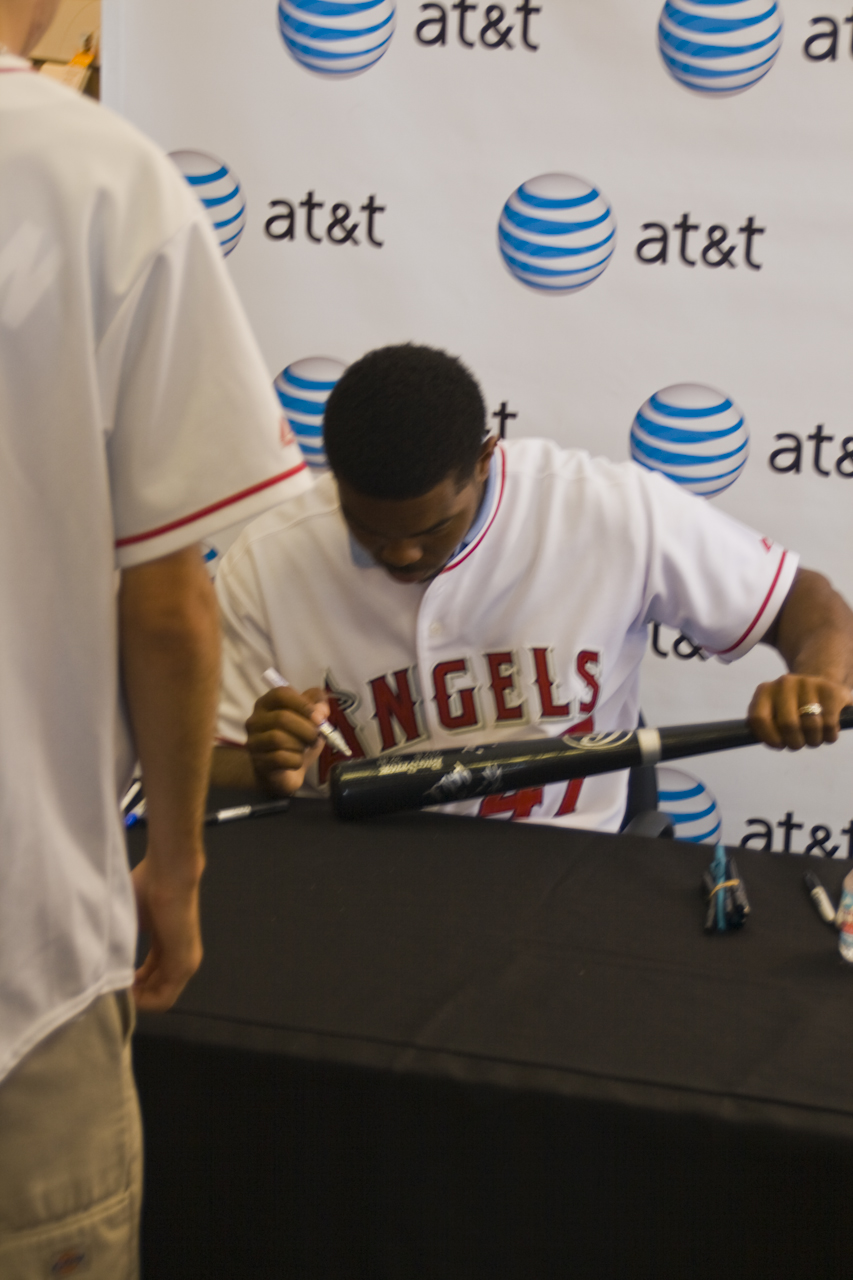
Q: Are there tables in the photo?
A: Yes, there is a table.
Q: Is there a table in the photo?
A: Yes, there is a table.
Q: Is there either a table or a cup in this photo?
A: Yes, there is a table.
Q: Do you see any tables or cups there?
A: Yes, there is a table.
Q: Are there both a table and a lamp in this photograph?
A: No, there is a table but no lamps.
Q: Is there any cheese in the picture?
A: No, there is no cheese.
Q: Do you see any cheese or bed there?
A: No, there are no cheese or beds.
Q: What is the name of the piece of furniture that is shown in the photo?
A: The piece of furniture is a table.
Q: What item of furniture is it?
A: The piece of furniture is a table.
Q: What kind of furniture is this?
A: This is a table.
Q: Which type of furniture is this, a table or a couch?
A: This is a table.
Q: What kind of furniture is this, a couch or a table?
A: This is a table.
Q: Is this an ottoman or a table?
A: This is a table.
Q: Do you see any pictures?
A: No, there are no pictures.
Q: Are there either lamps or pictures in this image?
A: No, there are no pictures or lamps.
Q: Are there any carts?
A: No, there are no carts.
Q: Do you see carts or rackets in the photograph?
A: No, there are no carts or rackets.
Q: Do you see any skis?
A: No, there are no skis.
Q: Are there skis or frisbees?
A: No, there are no skis or frisbees.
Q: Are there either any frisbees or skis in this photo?
A: No, there are no skis or frisbees.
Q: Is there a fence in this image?
A: No, there are no fences.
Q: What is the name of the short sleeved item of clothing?
A: The clothing item is a shirt.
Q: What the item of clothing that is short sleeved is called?
A: The clothing item is a shirt.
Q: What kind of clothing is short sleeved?
A: The clothing is a shirt.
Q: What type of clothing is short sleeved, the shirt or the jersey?
A: The shirt is short sleeved.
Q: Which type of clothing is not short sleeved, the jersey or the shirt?
A: The jersey is not short sleeved.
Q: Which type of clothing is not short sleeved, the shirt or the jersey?
A: The jersey is not short sleeved.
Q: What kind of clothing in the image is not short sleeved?
A: The clothing is a jersey.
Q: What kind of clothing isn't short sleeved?
A: The clothing is a jersey.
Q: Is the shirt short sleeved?
A: Yes, the shirt is short sleeved.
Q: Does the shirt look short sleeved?
A: Yes, the shirt is short sleeved.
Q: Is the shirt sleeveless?
A: No, the shirt is short sleeved.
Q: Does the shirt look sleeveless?
A: No, the shirt is short sleeved.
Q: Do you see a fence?
A: No, there are no fences.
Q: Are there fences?
A: No, there are no fences.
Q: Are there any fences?
A: No, there are no fences.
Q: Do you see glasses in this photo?
A: No, there are no glasses.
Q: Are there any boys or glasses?
A: No, there are no glasses or boys.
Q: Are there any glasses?
A: No, there are no glasses.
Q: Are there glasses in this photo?
A: No, there are no glasses.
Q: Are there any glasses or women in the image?
A: No, there are no glasses or women.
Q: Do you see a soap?
A: No, there are no soaps.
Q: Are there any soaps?
A: No, there are no soaps.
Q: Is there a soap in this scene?
A: No, there are no soaps.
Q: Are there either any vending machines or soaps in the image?
A: No, there are no soaps or vending machines.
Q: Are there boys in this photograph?
A: No, there are no boys.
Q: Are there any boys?
A: No, there are no boys.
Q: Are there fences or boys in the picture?
A: No, there are no boys or fences.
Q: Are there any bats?
A: Yes, there is a bat.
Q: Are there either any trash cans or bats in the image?
A: Yes, there is a bat.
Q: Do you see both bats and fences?
A: No, there is a bat but no fences.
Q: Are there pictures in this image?
A: No, there are no pictures.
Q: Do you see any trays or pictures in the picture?
A: No, there are no pictures or trays.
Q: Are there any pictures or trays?
A: No, there are no pictures or trays.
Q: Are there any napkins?
A: No, there are no napkins.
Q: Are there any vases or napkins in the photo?
A: No, there are no napkins or vases.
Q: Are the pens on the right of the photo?
A: Yes, the pens are on the right of the image.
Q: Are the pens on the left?
A: No, the pens are on the right of the image.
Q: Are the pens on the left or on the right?
A: The pens are on the right of the image.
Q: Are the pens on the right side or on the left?
A: The pens are on the right of the image.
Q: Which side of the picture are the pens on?
A: The pens are on the right of the image.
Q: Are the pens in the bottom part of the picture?
A: Yes, the pens are in the bottom of the image.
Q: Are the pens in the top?
A: No, the pens are in the bottom of the image.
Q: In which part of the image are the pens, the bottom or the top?
A: The pens are in the bottom of the image.